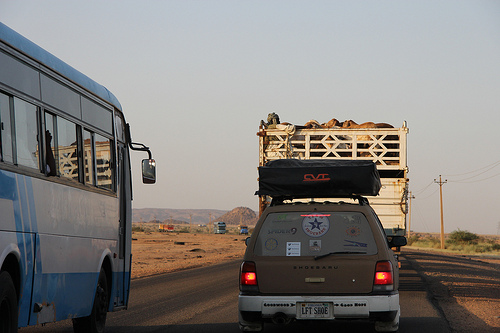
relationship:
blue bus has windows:
[0, 19, 155, 330] [3, 114, 120, 200]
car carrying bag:
[239, 194, 408, 332] [258, 158, 378, 194]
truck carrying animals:
[253, 111, 413, 245] [261, 110, 406, 165]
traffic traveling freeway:
[243, 157, 400, 319] [11, 212, 454, 331]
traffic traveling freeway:
[265, 117, 406, 234] [11, 212, 454, 331]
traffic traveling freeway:
[0, 26, 158, 331] [11, 212, 454, 331]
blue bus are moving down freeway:
[0, 19, 155, 330] [11, 212, 492, 331]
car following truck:
[180, 89, 444, 321] [255, 112, 411, 270]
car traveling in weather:
[239, 194, 408, 332] [2, 1, 497, 330]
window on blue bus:
[11, 96, 41, 170] [0, 19, 155, 330]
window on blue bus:
[42, 110, 55, 175] [0, 19, 155, 330]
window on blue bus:
[57, 116, 80, 182] [0, 19, 155, 330]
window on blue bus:
[83, 128, 94, 185] [0, 19, 155, 330]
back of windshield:
[241, 202, 400, 328] [248, 211, 368, 261]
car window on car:
[249, 209, 381, 259] [224, 155, 399, 321]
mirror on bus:
[137, 154, 161, 188] [21, 22, 186, 332]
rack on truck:
[254, 154, 382, 205] [249, 119, 430, 251]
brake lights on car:
[373, 269, 392, 285] [239, 194, 408, 332]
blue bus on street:
[0, 19, 155, 330] [41, 250, 452, 331]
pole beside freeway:
[432, 171, 452, 252] [11, 212, 454, 331]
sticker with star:
[302, 209, 332, 236] [299, 210, 335, 237]